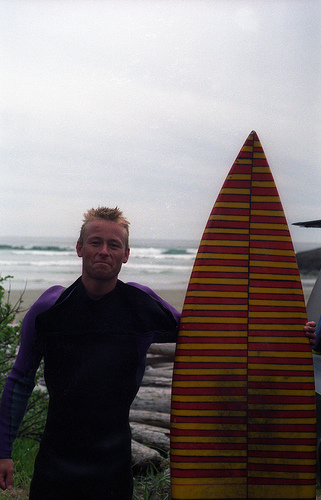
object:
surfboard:
[177, 131, 317, 500]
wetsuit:
[1, 278, 179, 498]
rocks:
[158, 243, 194, 260]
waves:
[5, 251, 53, 274]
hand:
[302, 321, 320, 352]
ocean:
[2, 237, 198, 296]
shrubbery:
[1, 272, 50, 461]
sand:
[3, 278, 195, 314]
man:
[1, 204, 186, 497]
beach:
[3, 286, 320, 500]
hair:
[77, 205, 133, 226]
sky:
[3, 4, 318, 235]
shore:
[1, 283, 183, 370]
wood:
[130, 431, 175, 466]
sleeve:
[1, 276, 59, 453]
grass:
[4, 434, 37, 498]